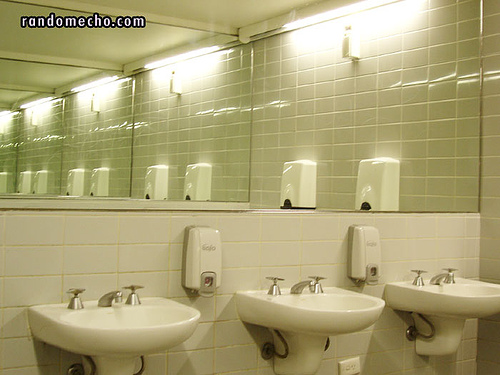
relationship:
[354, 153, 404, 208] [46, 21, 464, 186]
soap dispensers reflected in mirror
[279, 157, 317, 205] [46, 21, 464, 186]
soap dispensers reflected in mirror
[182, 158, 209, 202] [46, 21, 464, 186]
soap dispensers reflected in mirror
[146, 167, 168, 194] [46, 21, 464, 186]
soap dispensers reflected in mirror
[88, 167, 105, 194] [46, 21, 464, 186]
soap dispensers reflected in mirror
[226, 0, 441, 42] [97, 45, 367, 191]
wall lights reflected in mirror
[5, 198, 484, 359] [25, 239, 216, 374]
wall behind sink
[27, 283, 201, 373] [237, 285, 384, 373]
sink in middle of sink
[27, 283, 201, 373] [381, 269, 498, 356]
sink in middle of sink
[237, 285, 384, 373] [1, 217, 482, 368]
sink on wall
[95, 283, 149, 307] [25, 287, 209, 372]
faucet on sink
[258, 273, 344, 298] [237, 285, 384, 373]
faucet on sink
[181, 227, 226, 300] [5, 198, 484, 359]
dispenser on wall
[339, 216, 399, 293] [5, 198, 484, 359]
dispenser on wall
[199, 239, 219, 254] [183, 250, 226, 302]
logo on soap dispenser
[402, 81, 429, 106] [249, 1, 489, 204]
tile on wall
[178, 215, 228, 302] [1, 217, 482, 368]
soap dispenser on wall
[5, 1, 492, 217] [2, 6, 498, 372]
mirror in bathroom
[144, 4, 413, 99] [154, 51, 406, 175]
reflection on mirror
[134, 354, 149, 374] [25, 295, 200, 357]
tube below sink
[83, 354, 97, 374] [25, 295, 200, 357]
tube below sink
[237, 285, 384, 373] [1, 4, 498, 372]
sink on wall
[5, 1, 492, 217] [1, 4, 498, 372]
mirror on wall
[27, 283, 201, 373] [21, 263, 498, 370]
sink on row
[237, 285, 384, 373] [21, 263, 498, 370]
sink on row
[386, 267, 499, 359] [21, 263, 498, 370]
sink on row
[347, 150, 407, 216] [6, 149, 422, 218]
dryer has reflection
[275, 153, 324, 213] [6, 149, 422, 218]
dryer has reflection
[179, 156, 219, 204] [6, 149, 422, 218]
dryer has reflection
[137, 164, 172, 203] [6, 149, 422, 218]
dryer has reflection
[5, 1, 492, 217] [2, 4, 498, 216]
mirror has reflection